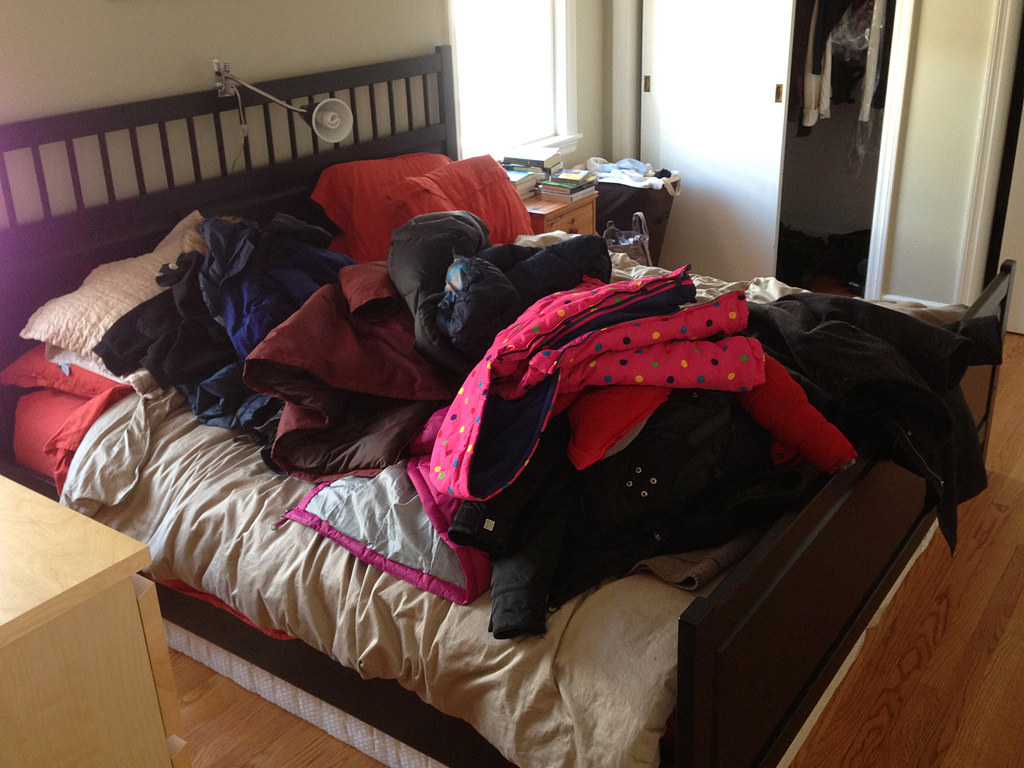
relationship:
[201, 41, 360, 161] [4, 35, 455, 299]
lamp attached to headboard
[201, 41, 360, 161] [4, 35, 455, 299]
lamp clipped on headboard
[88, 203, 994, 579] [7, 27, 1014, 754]
jackets are on bed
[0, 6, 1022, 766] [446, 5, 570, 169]
bedroom has window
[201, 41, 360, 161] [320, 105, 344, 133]
lamp has light bulb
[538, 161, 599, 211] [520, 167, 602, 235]
books are on dresser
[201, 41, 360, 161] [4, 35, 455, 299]
lamp hanging onto headboard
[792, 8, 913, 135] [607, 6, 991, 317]
clothes are in closet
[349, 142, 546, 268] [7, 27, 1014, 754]
pillow on bed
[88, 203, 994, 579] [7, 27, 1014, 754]
jackets on bed